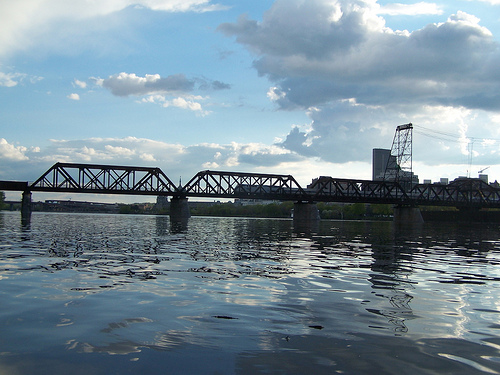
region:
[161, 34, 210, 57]
Part of light blue sky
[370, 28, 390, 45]
Part of white fluffy cloud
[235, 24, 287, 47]
Part of dark drifting cloud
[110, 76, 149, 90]
Part of dark drifting cloud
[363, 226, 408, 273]
Reflection of building in water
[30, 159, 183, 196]
Part of bridge to cross water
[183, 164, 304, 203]
Part of bridge to cross water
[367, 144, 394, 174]
Part of tall building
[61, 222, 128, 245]
Many ripples on water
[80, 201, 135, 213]
Far shoreline of water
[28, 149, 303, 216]
bridge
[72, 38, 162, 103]
white clouds in blue sky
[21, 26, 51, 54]
white clouds in blue sky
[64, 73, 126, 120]
white clouds in blue sky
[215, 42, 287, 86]
white clouds in blue sky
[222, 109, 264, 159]
white clouds in blue sky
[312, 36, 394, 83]
white clouds in blue sky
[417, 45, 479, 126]
white clouds in blue sky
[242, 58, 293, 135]
white clouds in blue sky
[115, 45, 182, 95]
white clouds in blue sky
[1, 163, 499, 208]
The bridge is black.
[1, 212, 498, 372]
The water is glassy with some ripples.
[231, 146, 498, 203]
A city skyline is behind the bridge.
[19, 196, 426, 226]
Concrete bases rise out of the water.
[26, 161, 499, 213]
The bridge has x shaped braces.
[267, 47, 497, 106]
Dark clouds are in the sky.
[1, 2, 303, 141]
Blue sky has a patch of clouds.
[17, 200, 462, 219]
A river bank has some trees and buildings.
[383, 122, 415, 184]
A tower is shaped like an A.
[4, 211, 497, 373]
The water is dark blue and reflective.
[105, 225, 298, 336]
the water is murky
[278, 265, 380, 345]
the water is murky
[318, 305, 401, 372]
the water is murky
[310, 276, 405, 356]
the water is murky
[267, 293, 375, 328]
the water is murky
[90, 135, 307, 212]
the bridge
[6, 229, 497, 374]
water with calm ripples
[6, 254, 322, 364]
reflection of the sky in water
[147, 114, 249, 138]
clear patch of blue sky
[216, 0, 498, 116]
large white puffy clouds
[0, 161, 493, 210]
bridge for crossing from one side to the other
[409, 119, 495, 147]
power lines for electricity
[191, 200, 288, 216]
row of medium sized trees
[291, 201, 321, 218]
concrete slabs supporting bridge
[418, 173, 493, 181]
cluster of city buildings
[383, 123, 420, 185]
tall structure connecting power lines